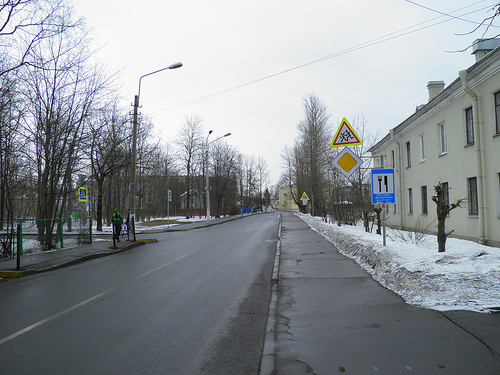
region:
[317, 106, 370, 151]
a triangular street sign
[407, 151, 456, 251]
a half of a tree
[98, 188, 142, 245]
two people talking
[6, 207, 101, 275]
a green fence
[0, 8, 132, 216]
bare tall trees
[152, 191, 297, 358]
an empty long street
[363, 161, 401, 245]
a sign with a knife and fork on it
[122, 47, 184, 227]
tall street lamp turned off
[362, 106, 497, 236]
cream short building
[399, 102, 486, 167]
windows on the side of the building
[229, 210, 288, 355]
this is a road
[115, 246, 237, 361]
the road is clear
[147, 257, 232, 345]
the road is tarmacked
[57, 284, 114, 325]
white strip is in the middle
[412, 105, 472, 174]
this is a building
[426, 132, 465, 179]
the walls are cream in color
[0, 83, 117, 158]
the trees are dry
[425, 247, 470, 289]
this is snow in the pavement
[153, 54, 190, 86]
this is a street light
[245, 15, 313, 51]
the sky is white in color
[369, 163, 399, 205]
a blue and white sign alongside a sidewalk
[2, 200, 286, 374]
a two lane road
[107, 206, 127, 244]
a person walking on a sidwalk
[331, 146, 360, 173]
a yellow and white sign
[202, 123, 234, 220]
a double headed streetlamp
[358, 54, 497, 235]
a long white building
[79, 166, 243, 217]
a brick building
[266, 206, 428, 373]
a cleared sidewalk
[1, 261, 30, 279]
a yellow curb on a sidewalk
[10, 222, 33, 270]
a green post on a sidewalk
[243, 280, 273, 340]
edge of a road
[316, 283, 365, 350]
part of a floor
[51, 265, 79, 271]
edge of a road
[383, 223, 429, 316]
edge of a snow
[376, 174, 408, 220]
part of a board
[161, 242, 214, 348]
this is a road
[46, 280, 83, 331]
this is a white strip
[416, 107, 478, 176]
this is a building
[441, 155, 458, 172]
the wall is white in color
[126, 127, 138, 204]
this is a pole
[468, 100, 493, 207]
this is a pipe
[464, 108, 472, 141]
this is the window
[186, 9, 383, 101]
this is the sky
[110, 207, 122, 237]
this is a man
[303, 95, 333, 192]
this is a tree